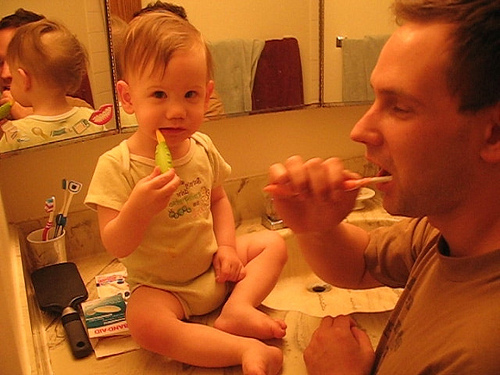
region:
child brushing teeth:
[98, 5, 240, 196]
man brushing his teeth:
[305, 18, 449, 300]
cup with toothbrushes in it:
[17, 160, 99, 261]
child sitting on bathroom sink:
[88, 27, 276, 372]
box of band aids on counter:
[52, 285, 150, 353]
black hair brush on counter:
[27, 280, 97, 361]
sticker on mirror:
[61, 85, 129, 150]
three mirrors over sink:
[5, 11, 442, 121]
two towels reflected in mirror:
[208, 31, 330, 123]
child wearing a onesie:
[62, 117, 299, 285]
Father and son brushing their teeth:
[69, 5, 492, 359]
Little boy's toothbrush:
[133, 120, 206, 199]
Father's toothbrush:
[257, 133, 424, 233]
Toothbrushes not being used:
[3, 177, 97, 291]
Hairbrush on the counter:
[15, 260, 120, 372]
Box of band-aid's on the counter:
[64, 288, 145, 370]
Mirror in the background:
[3, 2, 468, 144]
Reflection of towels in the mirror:
[201, 27, 418, 124]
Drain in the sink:
[283, 265, 372, 305]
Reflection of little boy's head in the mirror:
[11, 15, 103, 109]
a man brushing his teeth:
[269, 4, 498, 369]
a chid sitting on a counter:
[87, 11, 287, 371]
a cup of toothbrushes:
[21, 176, 81, 266]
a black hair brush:
[23, 261, 95, 358]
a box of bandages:
[76, 288, 148, 363]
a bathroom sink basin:
[241, 216, 406, 317]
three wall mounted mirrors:
[1, 0, 421, 155]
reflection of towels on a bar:
[194, 32, 309, 119]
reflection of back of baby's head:
[6, 19, 82, 114]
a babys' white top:
[87, 129, 238, 290]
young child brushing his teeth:
[52, 16, 327, 348]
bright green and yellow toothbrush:
[117, 118, 209, 201]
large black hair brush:
[14, 249, 111, 353]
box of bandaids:
[71, 291, 148, 356]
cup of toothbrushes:
[25, 171, 103, 271]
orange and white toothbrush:
[250, 148, 403, 220]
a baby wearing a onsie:
[67, 23, 316, 357]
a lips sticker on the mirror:
[78, 102, 124, 132]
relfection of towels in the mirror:
[174, 17, 338, 141]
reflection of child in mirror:
[2, 14, 105, 143]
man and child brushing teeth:
[89, 5, 491, 367]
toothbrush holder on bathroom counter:
[20, 168, 85, 271]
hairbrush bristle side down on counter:
[22, 257, 102, 363]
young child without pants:
[90, 6, 284, 373]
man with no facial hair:
[345, 7, 497, 226]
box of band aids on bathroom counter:
[67, 280, 148, 366]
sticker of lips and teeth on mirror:
[81, 95, 123, 132]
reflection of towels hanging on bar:
[172, 26, 312, 136]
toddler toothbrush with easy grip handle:
[147, 117, 179, 194]